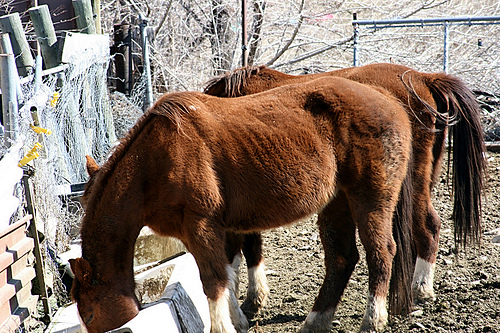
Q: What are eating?
A: Horses.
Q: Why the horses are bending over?
A: To eat.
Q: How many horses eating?
A: Two.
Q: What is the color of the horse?
A: Brown.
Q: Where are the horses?
A: In the fence.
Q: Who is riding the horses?
A: No one.